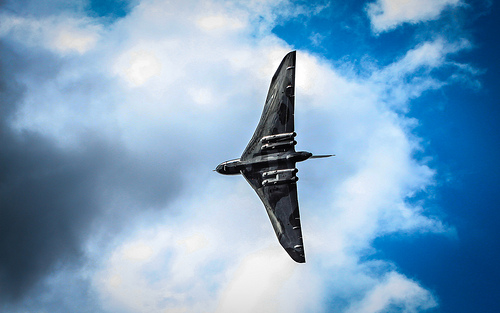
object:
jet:
[212, 50, 335, 263]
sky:
[0, 2, 499, 312]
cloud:
[348, 270, 442, 313]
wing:
[240, 50, 301, 160]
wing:
[240, 164, 306, 264]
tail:
[309, 154, 336, 159]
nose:
[213, 160, 227, 176]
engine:
[261, 140, 297, 151]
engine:
[260, 132, 297, 144]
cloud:
[362, 0, 458, 40]